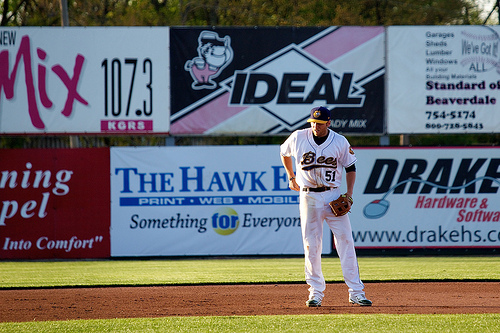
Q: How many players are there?
A: 1.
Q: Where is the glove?
A: Player's hand.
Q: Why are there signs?
A: Advertise businesses.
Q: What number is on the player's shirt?
A: 51.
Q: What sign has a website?
A: Drake.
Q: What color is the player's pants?
A: White.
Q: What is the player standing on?
A: Dirt on field.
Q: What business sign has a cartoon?
A: Ideal.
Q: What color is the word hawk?
A: Blue.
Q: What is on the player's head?
A: Cap.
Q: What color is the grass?
A: Green.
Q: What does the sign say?
A: Ideal.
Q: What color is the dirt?
A: Brown.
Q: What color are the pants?
A: White.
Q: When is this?
A: Day time.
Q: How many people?
A: 1.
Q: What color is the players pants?
A: White.